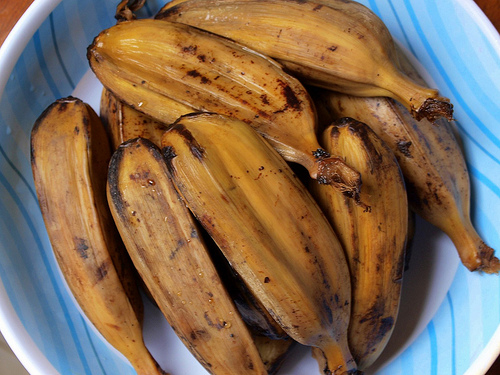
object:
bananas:
[85, 19, 361, 200]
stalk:
[299, 159, 359, 193]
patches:
[266, 76, 309, 116]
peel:
[156, 108, 357, 357]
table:
[0, 0, 500, 375]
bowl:
[0, 0, 500, 374]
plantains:
[27, 94, 168, 375]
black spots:
[106, 145, 123, 220]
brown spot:
[183, 65, 201, 81]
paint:
[28, 22, 87, 91]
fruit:
[161, 0, 447, 120]